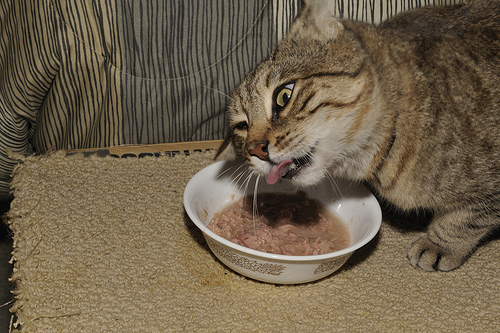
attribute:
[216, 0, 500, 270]
cat — eating, distracted, striped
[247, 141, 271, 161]
nose — brown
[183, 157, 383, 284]
bowl — white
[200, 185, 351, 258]
food — pink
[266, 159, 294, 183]
tongue — pink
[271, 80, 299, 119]
left eye — green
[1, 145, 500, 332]
rug — brown